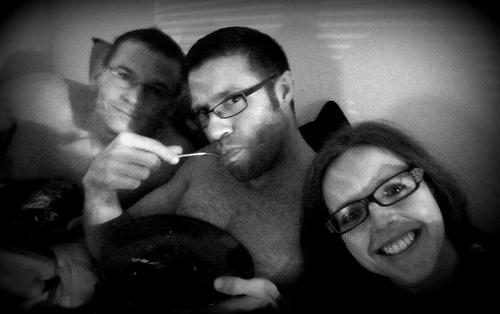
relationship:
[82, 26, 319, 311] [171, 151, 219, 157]
man has spoon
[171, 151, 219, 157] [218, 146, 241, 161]
spoon in mouth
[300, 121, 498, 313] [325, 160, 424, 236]
woman wearing glasses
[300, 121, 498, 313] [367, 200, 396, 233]
woman has a nose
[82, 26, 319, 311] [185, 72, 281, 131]
man wearing glasses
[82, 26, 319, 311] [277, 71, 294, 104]
man has left ear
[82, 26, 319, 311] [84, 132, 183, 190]
man has a right hand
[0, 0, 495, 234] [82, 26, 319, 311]
wall behind man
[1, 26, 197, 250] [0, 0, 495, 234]
man by wall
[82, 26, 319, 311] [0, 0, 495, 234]
man by wall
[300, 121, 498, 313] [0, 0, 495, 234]
woman by wall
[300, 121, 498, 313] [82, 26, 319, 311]
woman next to man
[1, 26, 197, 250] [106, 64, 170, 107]
man wearing glasses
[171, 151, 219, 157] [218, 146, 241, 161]
spoon in h mouth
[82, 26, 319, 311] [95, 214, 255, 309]
man holding plate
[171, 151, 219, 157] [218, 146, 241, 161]
spoon in mans mouth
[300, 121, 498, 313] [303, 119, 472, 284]
woman has hair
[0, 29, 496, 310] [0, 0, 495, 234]
people in front of wall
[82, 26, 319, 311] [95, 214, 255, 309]
man has plate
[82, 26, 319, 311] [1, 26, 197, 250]
man beside man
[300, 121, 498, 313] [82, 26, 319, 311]
woman in front of man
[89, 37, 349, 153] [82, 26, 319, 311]
pillow behind man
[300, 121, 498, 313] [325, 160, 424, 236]
woman has glasses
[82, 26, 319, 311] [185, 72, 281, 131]
man has glasses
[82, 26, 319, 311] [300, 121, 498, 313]
man next to woman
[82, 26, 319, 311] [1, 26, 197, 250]
man next to man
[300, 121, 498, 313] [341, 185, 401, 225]
woman has eyes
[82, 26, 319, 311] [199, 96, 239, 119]
man has eyes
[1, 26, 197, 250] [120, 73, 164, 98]
man has eyes